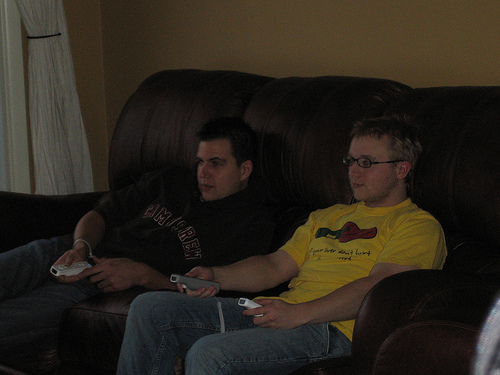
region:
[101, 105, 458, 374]
The man is sitting.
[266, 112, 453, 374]
The man is wearing glasses.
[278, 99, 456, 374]
The man has short hair.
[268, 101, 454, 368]
The glasses have wire frames.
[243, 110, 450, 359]
The man is wearing a shirt.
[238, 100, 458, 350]
The man's shirt is yellow.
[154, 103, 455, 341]
The man is holding two game controllers.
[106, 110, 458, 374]
The man is wearing blue jeans.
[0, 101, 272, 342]
The man is holding a game controller.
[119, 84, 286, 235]
The man has dark hair.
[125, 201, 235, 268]
A black shirt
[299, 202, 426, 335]
A yellow t-shirt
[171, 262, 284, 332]
Joysticks in the hands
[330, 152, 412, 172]
Glasses in the photo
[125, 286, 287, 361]
Jeans in the photo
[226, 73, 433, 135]
A couch in the photo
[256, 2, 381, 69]
A wall in the photo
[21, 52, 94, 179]
A curtain in the room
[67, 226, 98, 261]
A bracelet on the hand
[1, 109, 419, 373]
Two people seated on a couch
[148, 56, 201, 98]
Patch of dark leather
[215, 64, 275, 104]
Patch of dark leather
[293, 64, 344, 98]
Patch of dark leather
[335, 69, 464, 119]
Patch of dark leather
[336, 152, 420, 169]
Black rimmed galsses on face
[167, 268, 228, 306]
SIlver remote in hand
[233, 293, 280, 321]
White remote in hand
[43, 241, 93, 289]
White remote in hand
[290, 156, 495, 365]
Man yearing yellow shirt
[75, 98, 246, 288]
Man wearing dark colored shirt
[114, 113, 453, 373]
mean wearing glasses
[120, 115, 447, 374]
man with blond hair and black glasses on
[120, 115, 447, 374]
man in yellow t-shirt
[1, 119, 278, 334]
guy with dark hair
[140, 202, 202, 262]
red writing on black hoodie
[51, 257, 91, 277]
white wii control in hand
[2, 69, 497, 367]
large leather couch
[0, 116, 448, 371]
two men sitting on the couch together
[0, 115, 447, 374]
two guys playing Wii together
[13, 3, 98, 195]
part of white curtain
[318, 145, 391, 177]
These are glasses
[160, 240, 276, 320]
These are wii remotes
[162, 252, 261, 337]
The remotes are white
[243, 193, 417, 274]
This is a yellow shirt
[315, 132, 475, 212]
The hair is blonde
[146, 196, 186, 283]
This is a red shirt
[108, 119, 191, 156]
This is a couch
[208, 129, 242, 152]
The hair is brown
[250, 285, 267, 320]
These are fingers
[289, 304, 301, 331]
This is a wrist